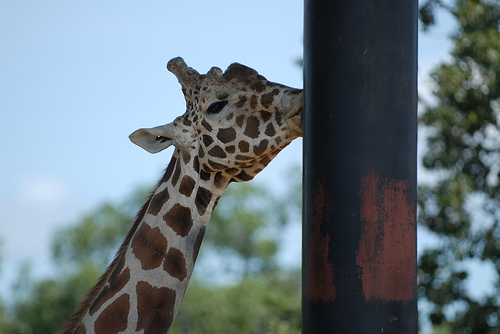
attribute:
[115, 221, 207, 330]
spots — brown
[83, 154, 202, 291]
neck — long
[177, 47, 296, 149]
head — up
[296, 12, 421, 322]
pole — tall, faded, metal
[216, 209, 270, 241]
trees — distant, here, present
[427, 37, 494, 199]
tree — distant, here, present, blurred, leafy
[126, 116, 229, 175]
ear — down-turned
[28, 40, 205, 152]
sky — clear, sunny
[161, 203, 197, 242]
spot — brown, here, present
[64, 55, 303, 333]
giraffe — spotted, brown, here, present, licking, standing, kissing, white